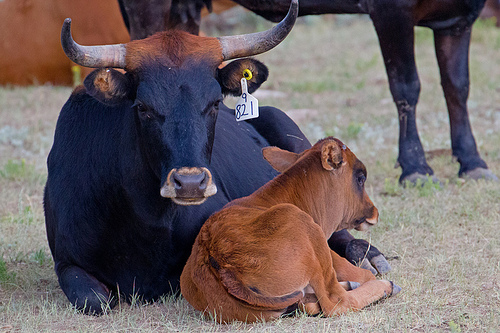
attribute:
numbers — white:
[232, 99, 262, 122]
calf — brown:
[187, 134, 399, 322]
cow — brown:
[177, 136, 397, 310]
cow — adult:
[39, 2, 391, 277]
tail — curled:
[208, 267, 305, 304]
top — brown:
[124, 29, 224, 75]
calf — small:
[166, 129, 404, 332]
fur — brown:
[121, 22, 249, 81]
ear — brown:
[305, 131, 358, 169]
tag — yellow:
[218, 57, 298, 135]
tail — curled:
[206, 255, 315, 321]